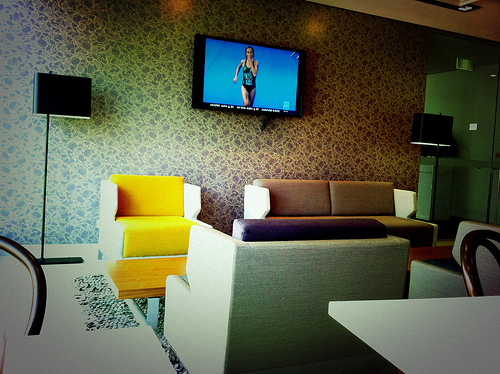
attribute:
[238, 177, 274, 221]
arm — tan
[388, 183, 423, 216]
arm — tan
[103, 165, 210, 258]
chair — bright, yellow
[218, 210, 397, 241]
purple cushion — purple 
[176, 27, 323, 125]
tv — flat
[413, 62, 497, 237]
cabinets — green, colored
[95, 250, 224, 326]
coffee table — wooden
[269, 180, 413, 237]
fabric — tan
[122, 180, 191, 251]
fabric — yellow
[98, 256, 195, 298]
table top — wood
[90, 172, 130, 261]
chair frame — white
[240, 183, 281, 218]
loveseat frame — white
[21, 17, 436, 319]
room — dim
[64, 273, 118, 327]
rug — small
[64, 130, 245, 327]
chair — yellow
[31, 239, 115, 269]
base — black, rectangular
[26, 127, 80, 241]
post — black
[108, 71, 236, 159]
wallpaper — patterned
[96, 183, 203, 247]
chair — bright yellow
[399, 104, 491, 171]
lamp — black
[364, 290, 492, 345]
item — white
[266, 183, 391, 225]
cushions — brown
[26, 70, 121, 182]
box — black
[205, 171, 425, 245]
chair — brown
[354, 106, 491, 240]
lamp — black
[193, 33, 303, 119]
tv — flat, hanging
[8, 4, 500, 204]
wall — gray, purple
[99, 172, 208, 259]
chair — yellow, white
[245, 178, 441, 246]
loveseat — brown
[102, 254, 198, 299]
table — gray, yellow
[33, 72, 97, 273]
lamp — black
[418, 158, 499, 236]
boxes — green